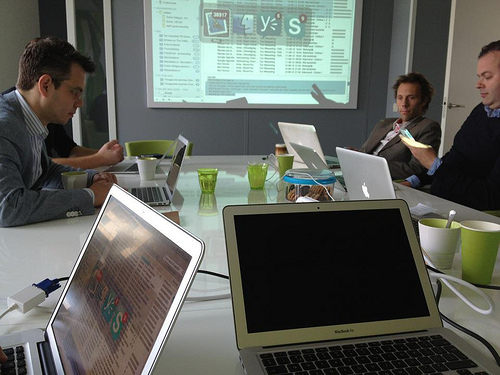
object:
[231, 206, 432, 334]
screen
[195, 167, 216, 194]
cup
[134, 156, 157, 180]
cup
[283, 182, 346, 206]
tupperware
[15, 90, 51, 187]
shirt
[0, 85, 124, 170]
man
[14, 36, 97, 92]
brown hair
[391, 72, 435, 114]
brown hair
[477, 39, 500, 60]
brown hair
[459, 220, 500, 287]
green cup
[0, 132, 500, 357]
ground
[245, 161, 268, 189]
glass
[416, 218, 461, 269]
glass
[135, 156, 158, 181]
glass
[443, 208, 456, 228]
utensil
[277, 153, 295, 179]
mug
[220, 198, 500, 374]
laptop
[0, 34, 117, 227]
man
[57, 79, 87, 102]
glasses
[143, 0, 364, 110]
projection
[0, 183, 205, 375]
laptop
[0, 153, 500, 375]
table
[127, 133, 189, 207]
laptop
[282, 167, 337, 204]
bowl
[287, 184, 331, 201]
cookies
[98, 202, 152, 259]
reflection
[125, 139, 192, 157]
chair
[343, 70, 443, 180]
man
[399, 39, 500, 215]
man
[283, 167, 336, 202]
container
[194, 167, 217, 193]
glass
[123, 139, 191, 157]
back